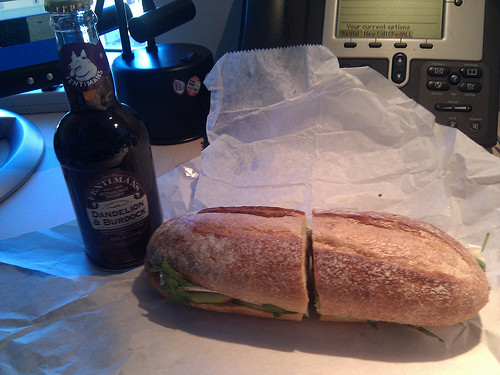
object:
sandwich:
[144, 206, 492, 326]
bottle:
[48, 2, 163, 272]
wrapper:
[0, 43, 499, 373]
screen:
[336, 3, 439, 38]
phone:
[214, 0, 499, 149]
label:
[85, 168, 150, 247]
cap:
[43, 1, 95, 11]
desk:
[7, 95, 499, 370]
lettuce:
[151, 264, 204, 294]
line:
[296, 215, 330, 320]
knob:
[27, 77, 37, 86]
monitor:
[1, 1, 63, 101]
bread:
[312, 209, 488, 324]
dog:
[64, 50, 103, 83]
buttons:
[424, 62, 451, 76]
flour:
[333, 263, 399, 292]